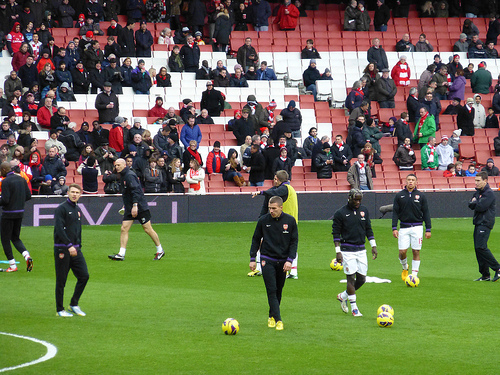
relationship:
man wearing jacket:
[411, 104, 437, 146] [412, 113, 436, 144]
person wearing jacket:
[200, 138, 229, 165] [205, 149, 224, 172]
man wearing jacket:
[107, 158, 166, 260] [117, 170, 145, 209]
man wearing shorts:
[107, 158, 166, 260] [124, 210, 149, 227]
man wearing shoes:
[107, 158, 166, 260] [108, 248, 165, 260]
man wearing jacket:
[384, 173, 437, 285] [389, 191, 431, 226]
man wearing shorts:
[384, 173, 437, 285] [397, 226, 424, 254]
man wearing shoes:
[384, 173, 437, 285] [399, 271, 412, 281]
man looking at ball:
[249, 196, 298, 330] [221, 317, 239, 334]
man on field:
[108, 158, 165, 261] [5, 213, 498, 370]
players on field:
[50, 180, 93, 323] [5, 213, 498, 370]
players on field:
[1, 157, 31, 273] [5, 213, 498, 370]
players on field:
[330, 183, 379, 318] [5, 213, 498, 370]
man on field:
[392, 174, 431, 281] [5, 213, 498, 370]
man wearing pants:
[249, 190, 299, 334] [262, 257, 290, 322]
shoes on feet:
[262, 315, 297, 333] [252, 260, 296, 337]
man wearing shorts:
[392, 174, 431, 281] [373, 227, 433, 262]